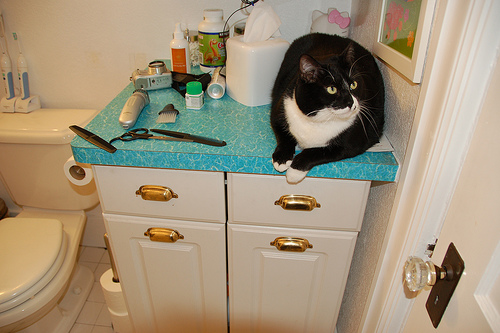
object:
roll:
[69, 165, 86, 181]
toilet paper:
[63, 152, 93, 187]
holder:
[103, 232, 120, 283]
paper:
[99, 268, 133, 314]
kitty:
[310, 8, 352, 37]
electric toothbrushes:
[10, 31, 30, 99]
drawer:
[225, 173, 373, 232]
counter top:
[70, 59, 398, 165]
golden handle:
[143, 227, 184, 243]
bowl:
[1, 231, 78, 333]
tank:
[0, 108, 100, 209]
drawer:
[92, 165, 225, 223]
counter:
[69, 59, 398, 183]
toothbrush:
[0, 14, 15, 100]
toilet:
[1, 108, 112, 333]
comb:
[69, 124, 118, 153]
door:
[365, 0, 499, 333]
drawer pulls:
[273, 195, 320, 212]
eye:
[326, 86, 337, 94]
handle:
[134, 185, 178, 202]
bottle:
[185, 81, 205, 110]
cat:
[270, 32, 385, 184]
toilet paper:
[108, 307, 133, 332]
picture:
[380, 0, 426, 60]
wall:
[339, 0, 443, 330]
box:
[224, 35, 290, 109]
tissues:
[243, 3, 283, 42]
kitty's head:
[294, 42, 368, 120]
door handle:
[402, 256, 455, 292]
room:
[2, 0, 497, 331]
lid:
[186, 81, 202, 95]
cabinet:
[93, 164, 373, 330]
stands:
[15, 94, 41, 114]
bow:
[328, 9, 349, 29]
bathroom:
[0, 0, 500, 333]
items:
[117, 88, 151, 130]